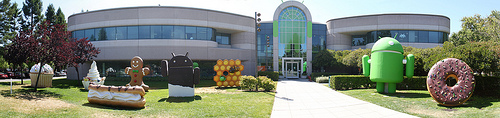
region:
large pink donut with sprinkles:
[427, 57, 476, 105]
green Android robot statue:
[361, 35, 414, 95]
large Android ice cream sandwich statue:
[162, 53, 197, 102]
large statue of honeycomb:
[213, 57, 242, 87]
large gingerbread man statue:
[127, 58, 148, 88]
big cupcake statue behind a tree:
[29, 61, 59, 88]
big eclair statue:
[84, 84, 144, 107]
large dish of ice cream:
[82, 60, 104, 86]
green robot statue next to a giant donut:
[362, 31, 474, 103]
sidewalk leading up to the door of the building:
[282, 73, 308, 116]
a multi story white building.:
[56, 6, 458, 91]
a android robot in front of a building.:
[354, 23, 417, 92]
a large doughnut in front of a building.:
[412, 39, 475, 114]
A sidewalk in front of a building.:
[264, 76, 430, 116]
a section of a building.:
[324, 6, 454, 56]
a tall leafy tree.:
[0, 0, 92, 80]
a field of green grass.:
[1, 62, 275, 113]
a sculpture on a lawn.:
[201, 54, 248, 100]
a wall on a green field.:
[87, 78, 155, 111]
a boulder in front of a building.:
[27, 45, 60, 92]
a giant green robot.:
[349, 26, 431, 94]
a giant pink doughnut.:
[423, 33, 475, 107]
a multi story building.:
[66, 0, 271, 82]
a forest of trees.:
[0, 0, 105, 91]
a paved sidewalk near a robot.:
[264, 79, 429, 116]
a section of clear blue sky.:
[0, 0, 497, 36]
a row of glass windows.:
[67, 23, 232, 45]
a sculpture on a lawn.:
[74, 76, 164, 113]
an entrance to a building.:
[277, 54, 311, 81]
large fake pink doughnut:
[412, 50, 480, 115]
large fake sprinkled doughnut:
[416, 54, 483, 107]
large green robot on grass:
[317, 25, 423, 113]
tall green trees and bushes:
[400, 7, 488, 71]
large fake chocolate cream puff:
[92, 80, 157, 117]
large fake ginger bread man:
[114, 54, 150, 96]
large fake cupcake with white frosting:
[17, 55, 66, 99]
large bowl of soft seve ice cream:
[55, 52, 115, 110]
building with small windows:
[53, 0, 226, 76]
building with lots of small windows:
[263, 3, 315, 78]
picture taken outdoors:
[18, 15, 483, 111]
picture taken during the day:
[41, 11, 477, 71]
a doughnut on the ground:
[426, 40, 466, 117]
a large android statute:
[361, 26, 423, 113]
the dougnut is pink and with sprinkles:
[428, 57, 498, 112]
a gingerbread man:
[123, 53, 150, 81]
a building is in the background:
[53, 6, 456, 66]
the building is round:
[90, 8, 237, 70]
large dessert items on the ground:
[26, 64, 442, 110]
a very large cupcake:
[26, 68, 56, 89]